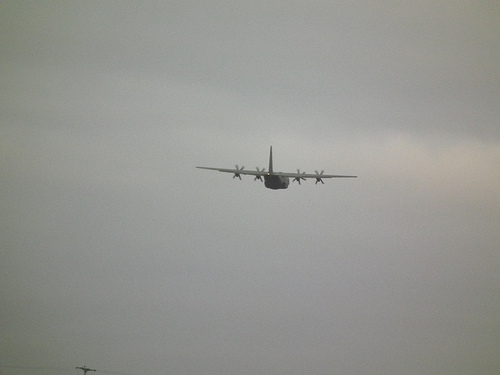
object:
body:
[265, 172, 290, 190]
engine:
[314, 171, 324, 184]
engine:
[295, 175, 300, 181]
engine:
[256, 174, 262, 179]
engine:
[234, 171, 239, 177]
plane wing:
[195, 165, 264, 179]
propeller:
[254, 167, 266, 182]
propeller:
[232, 163, 244, 180]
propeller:
[312, 169, 325, 184]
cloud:
[358, 123, 498, 187]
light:
[267, 173, 270, 175]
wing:
[195, 159, 267, 178]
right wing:
[285, 170, 359, 185]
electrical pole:
[75, 365, 97, 373]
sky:
[1, 2, 496, 370]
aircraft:
[196, 144, 359, 192]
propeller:
[293, 168, 307, 185]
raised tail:
[267, 146, 275, 172]